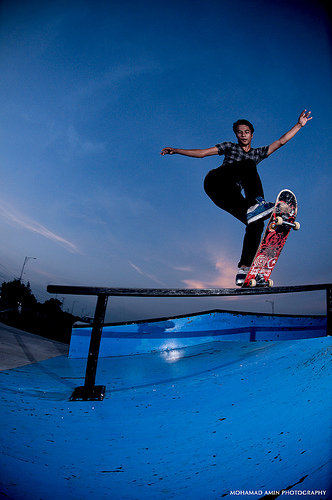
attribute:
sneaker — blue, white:
[242, 192, 279, 231]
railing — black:
[40, 269, 331, 403]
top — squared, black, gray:
[216, 140, 271, 165]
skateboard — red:
[158, 108, 314, 285]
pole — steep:
[17, 254, 38, 278]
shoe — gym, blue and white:
[233, 265, 247, 282]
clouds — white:
[8, 199, 63, 244]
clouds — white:
[5, 194, 157, 282]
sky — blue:
[8, 9, 146, 263]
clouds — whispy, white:
[23, 202, 116, 262]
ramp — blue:
[1, 334, 329, 499]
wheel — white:
[293, 219, 302, 234]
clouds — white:
[7, 185, 245, 291]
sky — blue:
[8, 10, 315, 291]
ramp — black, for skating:
[5, 282, 328, 498]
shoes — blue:
[226, 203, 308, 258]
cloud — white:
[2, 209, 77, 252]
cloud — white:
[123, 257, 165, 287]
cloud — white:
[166, 264, 197, 272]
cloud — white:
[178, 245, 243, 289]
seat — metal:
[45, 284, 228, 401]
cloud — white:
[61, 82, 105, 155]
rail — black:
[42, 275, 330, 327]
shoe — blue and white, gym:
[234, 197, 285, 224]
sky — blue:
[1, 3, 330, 336]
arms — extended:
[152, 106, 330, 162]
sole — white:
[228, 276, 276, 289]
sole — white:
[240, 208, 291, 228]